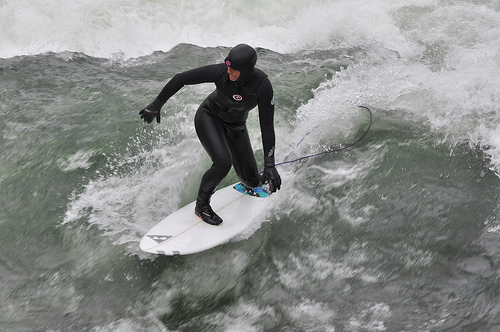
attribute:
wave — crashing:
[0, 0, 211, 65]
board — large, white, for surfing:
[141, 159, 298, 256]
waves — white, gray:
[66, 179, 253, 301]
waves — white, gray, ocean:
[52, 42, 220, 87]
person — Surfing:
[137, 43, 282, 225]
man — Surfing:
[138, 34, 286, 230]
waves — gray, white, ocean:
[0, 0, 497, 330]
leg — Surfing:
[215, 118, 271, 181]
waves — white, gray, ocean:
[59, 137, 101, 167]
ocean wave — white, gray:
[50, 100, 280, 271]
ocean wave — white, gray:
[49, 145, 103, 173]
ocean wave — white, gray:
[279, 0, 499, 172]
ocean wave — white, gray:
[0, 0, 425, 65]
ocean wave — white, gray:
[270, 245, 390, 287]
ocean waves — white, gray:
[3, 2, 496, 327]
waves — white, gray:
[287, 157, 499, 329]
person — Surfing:
[134, 32, 286, 233]